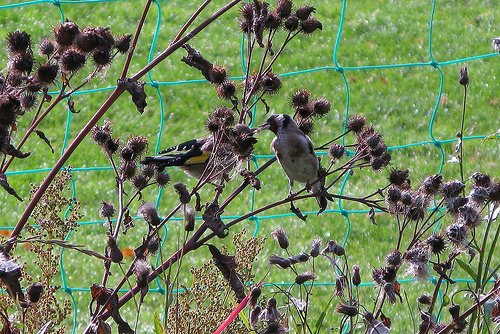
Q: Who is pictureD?
A: No one.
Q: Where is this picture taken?
A: On branches.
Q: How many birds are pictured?
A: 2.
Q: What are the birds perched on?
A: Branches.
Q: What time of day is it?
A: Day time.